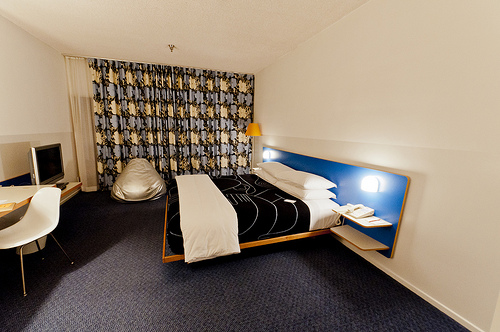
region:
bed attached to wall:
[158, 159, 340, 263]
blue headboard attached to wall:
[261, 142, 411, 259]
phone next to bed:
[335, 202, 375, 224]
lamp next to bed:
[245, 121, 262, 167]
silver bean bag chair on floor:
[111, 155, 165, 202]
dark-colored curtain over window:
[89, 55, 255, 191]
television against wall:
[29, 141, 66, 187]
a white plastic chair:
[0, 185, 78, 297]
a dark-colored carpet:
[0, 188, 471, 330]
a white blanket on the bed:
[173, 172, 240, 264]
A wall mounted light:
[350, 165, 385, 195]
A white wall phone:
[340, 195, 375, 215]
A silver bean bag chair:
[100, 135, 165, 200]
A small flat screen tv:
[15, 130, 80, 185]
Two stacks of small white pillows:
[250, 150, 345, 205]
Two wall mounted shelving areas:
[325, 195, 390, 260]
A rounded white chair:
[0, 175, 80, 310]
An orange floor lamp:
[235, 110, 260, 170]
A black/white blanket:
[160, 165, 310, 250]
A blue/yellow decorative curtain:
[78, 53, 261, 183]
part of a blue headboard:
[310, 155, 408, 193]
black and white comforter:
[230, 186, 277, 214]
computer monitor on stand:
[24, 138, 76, 190]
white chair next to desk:
[2, 179, 77, 296]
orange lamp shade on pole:
[241, 113, 263, 181]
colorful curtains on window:
[95, 59, 200, 131]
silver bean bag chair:
[110, 153, 177, 205]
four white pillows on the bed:
[252, 159, 337, 200]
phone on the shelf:
[335, 201, 373, 224]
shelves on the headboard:
[334, 220, 389, 261]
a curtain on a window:
[74, 55, 256, 161]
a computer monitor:
[29, 140, 67, 189]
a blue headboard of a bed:
[263, 145, 409, 218]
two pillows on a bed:
[274, 167, 337, 205]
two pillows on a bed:
[249, 157, 288, 183]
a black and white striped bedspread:
[217, 164, 306, 246]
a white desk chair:
[1, 185, 66, 302]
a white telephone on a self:
[339, 200, 375, 221]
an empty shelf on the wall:
[329, 226, 391, 254]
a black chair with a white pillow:
[95, 152, 178, 226]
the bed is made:
[153, 160, 335, 255]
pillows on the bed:
[251, 154, 335, 203]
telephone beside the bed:
[331, 192, 378, 214]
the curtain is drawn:
[80, 58, 255, 162]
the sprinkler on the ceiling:
[160, 41, 181, 52]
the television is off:
[18, 138, 77, 180]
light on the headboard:
[253, 147, 273, 159]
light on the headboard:
[346, 174, 382, 194]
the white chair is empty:
[7, 190, 65, 257]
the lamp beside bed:
[239, 118, 269, 164]